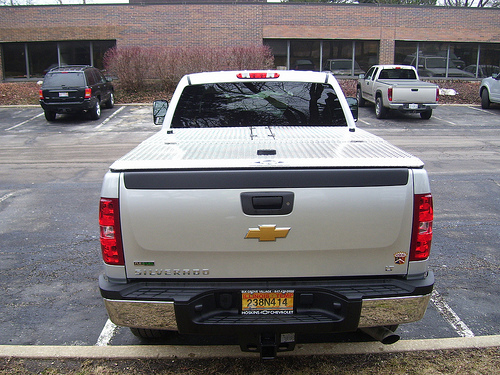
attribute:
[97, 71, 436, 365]
truck — parked, chevrolet, silverado, white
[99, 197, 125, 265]
tail light — red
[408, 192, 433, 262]
tail light — red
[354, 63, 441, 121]
truck — parked, gray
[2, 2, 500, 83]
building — brick, red, brown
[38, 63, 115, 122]
car — black, parked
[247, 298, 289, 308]
number — black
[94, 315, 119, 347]
line — white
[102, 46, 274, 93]
bushes — red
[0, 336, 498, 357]
curb — cement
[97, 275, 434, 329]
bumper — chrome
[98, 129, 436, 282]
flatbed — covered